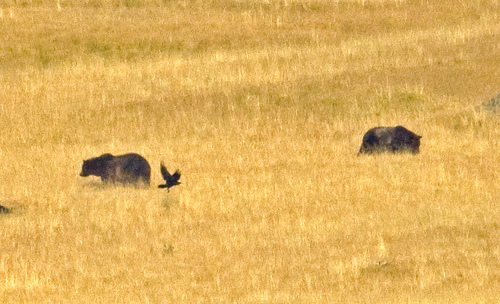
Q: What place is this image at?
A: It is at the field.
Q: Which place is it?
A: It is a field.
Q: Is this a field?
A: Yes, it is a field.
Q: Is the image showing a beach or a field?
A: It is showing a field.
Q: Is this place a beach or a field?
A: It is a field.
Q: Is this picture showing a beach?
A: No, the picture is showing a field.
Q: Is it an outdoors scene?
A: Yes, it is outdoors.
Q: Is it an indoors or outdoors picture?
A: It is outdoors.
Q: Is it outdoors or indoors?
A: It is outdoors.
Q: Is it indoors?
A: No, it is outdoors.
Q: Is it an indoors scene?
A: No, it is outdoors.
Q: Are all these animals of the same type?
A: No, there are both birds and bears.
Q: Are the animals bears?
A: No, there are both birds and bears.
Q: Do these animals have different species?
A: Yes, they are birds and bears.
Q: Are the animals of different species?
A: Yes, they are birds and bears.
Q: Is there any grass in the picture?
A: Yes, there is grass.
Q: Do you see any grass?
A: Yes, there is grass.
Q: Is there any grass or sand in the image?
A: Yes, there is grass.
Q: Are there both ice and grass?
A: No, there is grass but no ice.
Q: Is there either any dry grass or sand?
A: Yes, there is dry grass.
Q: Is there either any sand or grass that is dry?
A: Yes, the grass is dry.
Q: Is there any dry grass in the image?
A: Yes, there is dry grass.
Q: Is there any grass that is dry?
A: Yes, there is grass that is dry.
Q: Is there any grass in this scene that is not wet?
A: Yes, there is dry grass.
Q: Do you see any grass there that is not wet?
A: Yes, there is dry grass.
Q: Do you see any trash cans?
A: No, there are no trash cans.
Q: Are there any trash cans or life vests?
A: No, there are no trash cans or life vests.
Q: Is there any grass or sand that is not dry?
A: No, there is grass but it is dry.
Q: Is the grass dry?
A: Yes, the grass is dry.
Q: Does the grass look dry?
A: Yes, the grass is dry.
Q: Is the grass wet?
A: No, the grass is dry.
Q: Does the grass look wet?
A: No, the grass is dry.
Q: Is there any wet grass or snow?
A: No, there is grass but it is dry.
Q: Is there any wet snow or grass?
A: No, there is grass but it is dry.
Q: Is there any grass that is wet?
A: No, there is grass but it is dry.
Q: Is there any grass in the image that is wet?
A: No, there is grass but it is dry.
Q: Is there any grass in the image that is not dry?
A: No, there is grass but it is dry.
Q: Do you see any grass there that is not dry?
A: No, there is grass but it is dry.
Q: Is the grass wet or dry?
A: The grass is dry.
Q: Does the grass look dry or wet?
A: The grass is dry.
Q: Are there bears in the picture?
A: Yes, there is a bear.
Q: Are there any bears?
A: Yes, there is a bear.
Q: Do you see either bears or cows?
A: Yes, there is a bear.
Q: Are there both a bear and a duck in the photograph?
A: No, there is a bear but no ducks.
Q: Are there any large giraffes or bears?
A: Yes, there is a large bear.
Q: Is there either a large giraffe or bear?
A: Yes, there is a large bear.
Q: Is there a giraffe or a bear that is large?
A: Yes, the bear is large.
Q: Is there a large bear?
A: Yes, there is a large bear.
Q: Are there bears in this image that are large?
A: Yes, there is a bear that is large.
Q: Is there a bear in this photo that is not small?
A: Yes, there is a large bear.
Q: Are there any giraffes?
A: No, there are no giraffes.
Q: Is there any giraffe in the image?
A: No, there are no giraffes.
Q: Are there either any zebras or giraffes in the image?
A: No, there are no giraffes or zebras.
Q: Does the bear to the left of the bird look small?
A: No, the bear is large.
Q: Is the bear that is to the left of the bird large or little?
A: The bear is large.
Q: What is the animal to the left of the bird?
A: The animal is a bear.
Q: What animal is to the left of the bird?
A: The animal is a bear.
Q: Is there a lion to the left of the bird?
A: No, there is a bear to the left of the bird.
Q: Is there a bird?
A: Yes, there is a bird.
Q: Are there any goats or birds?
A: Yes, there is a bird.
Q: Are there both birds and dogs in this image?
A: No, there is a bird but no dogs.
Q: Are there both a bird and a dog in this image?
A: No, there is a bird but no dogs.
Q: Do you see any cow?
A: No, there are no cows.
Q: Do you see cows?
A: No, there are no cows.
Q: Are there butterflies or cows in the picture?
A: No, there are no cows or butterflies.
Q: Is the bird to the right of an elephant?
A: No, the bird is to the right of a bear.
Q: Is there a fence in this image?
A: No, there are no fences.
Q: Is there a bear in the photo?
A: Yes, there is a bear.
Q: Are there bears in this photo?
A: Yes, there is a bear.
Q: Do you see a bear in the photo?
A: Yes, there is a bear.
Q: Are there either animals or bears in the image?
A: Yes, there is a bear.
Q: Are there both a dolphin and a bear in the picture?
A: No, there is a bear but no dolphins.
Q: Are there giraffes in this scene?
A: No, there are no giraffes.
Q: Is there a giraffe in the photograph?
A: No, there are no giraffes.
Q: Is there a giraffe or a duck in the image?
A: No, there are no giraffes or ducks.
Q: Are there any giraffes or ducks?
A: No, there are no giraffes or ducks.